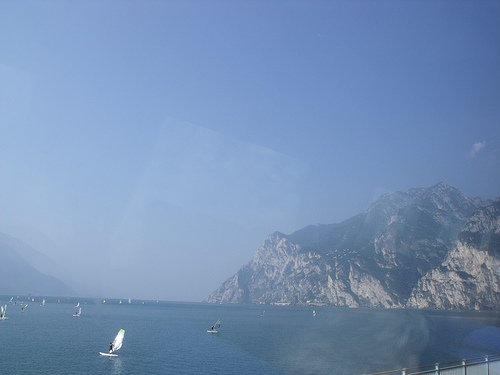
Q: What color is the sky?
A: Blue.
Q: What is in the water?
A: Boats.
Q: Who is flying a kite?
A: No one.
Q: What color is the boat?
A: White.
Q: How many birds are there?
A: None.